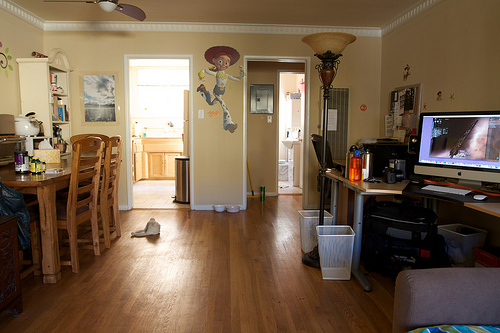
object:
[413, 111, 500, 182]
tv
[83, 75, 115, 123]
picture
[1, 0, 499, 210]
wall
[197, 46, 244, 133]
picture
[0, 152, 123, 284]
desk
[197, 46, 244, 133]
decal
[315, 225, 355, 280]
basket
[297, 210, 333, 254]
basket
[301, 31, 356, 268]
lamp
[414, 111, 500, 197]
computer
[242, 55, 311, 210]
doorway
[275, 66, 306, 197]
bathroom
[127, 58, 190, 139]
daylight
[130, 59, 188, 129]
window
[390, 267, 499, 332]
couch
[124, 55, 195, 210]
frame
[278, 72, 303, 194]
bathroom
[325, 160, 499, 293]
desk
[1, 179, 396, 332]
floors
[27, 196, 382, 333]
wood grain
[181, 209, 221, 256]
part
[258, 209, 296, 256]
part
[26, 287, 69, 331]
part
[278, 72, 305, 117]
light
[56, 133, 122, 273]
chairs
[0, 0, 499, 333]
house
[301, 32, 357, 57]
shade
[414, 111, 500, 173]
computer monitor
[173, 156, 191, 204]
can